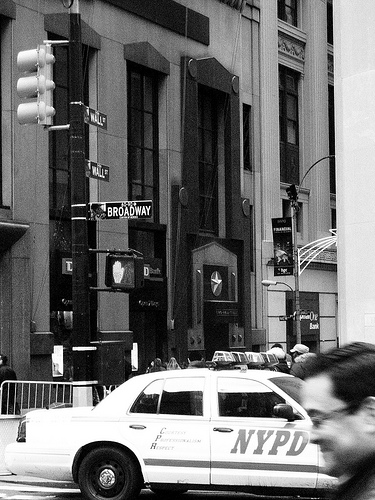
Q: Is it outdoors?
A: Yes, it is outdoors.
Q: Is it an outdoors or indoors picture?
A: It is outdoors.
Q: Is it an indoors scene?
A: No, it is outdoors.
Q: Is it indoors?
A: No, it is outdoors.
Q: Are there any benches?
A: No, there are no benches.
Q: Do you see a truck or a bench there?
A: No, there are no benches or trucks.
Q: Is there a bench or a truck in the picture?
A: No, there are no benches or trucks.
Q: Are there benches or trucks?
A: No, there are no benches or trucks.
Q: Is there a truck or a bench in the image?
A: No, there are no benches or trucks.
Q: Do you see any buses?
A: No, there are no buses.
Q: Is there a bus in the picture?
A: No, there are no buses.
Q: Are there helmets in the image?
A: No, there are no helmets.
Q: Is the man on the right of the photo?
A: Yes, the man is on the right of the image.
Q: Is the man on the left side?
A: No, the man is on the right of the image.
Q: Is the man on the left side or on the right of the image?
A: The man is on the right of the image.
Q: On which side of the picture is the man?
A: The man is on the right of the image.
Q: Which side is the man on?
A: The man is on the right of the image.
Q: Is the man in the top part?
A: No, the man is in the bottom of the image.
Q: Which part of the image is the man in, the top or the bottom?
A: The man is in the bottom of the image.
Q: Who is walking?
A: The man is walking.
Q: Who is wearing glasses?
A: The man is wearing glasses.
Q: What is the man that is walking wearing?
A: The man is wearing glasses.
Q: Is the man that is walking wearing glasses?
A: Yes, the man is wearing glasses.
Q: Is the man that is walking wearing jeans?
A: No, the man is wearing glasses.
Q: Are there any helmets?
A: No, there are no helmets.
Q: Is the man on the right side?
A: Yes, the man is on the right of the image.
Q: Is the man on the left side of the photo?
A: No, the man is on the right of the image.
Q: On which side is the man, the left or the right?
A: The man is on the right of the image.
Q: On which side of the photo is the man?
A: The man is on the right of the image.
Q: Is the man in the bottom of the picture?
A: Yes, the man is in the bottom of the image.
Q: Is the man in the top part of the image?
A: No, the man is in the bottom of the image.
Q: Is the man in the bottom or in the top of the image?
A: The man is in the bottom of the image.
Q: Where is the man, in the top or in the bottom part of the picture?
A: The man is in the bottom of the image.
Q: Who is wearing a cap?
A: The man is wearing a cap.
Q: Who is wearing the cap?
A: The man is wearing a cap.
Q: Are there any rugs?
A: No, there are no rugs.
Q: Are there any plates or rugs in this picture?
A: No, there are no rugs or plates.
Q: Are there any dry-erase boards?
A: No, there are no dry-erase boards.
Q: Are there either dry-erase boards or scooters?
A: No, there are no dry-erase boards or scooters.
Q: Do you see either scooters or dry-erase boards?
A: No, there are no dry-erase boards or scooters.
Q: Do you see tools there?
A: No, there are no tools.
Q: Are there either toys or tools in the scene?
A: No, there are no tools or toys.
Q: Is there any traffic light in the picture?
A: Yes, there is a traffic light.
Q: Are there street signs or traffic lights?
A: Yes, there is a traffic light.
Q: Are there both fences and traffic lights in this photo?
A: Yes, there are both a traffic light and a fence.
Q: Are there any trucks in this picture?
A: No, there are no trucks.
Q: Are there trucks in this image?
A: No, there are no trucks.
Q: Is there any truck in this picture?
A: No, there are no trucks.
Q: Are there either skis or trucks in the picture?
A: No, there are no trucks or skis.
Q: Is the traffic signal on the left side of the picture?
A: Yes, the traffic signal is on the left of the image.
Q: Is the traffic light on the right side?
A: No, the traffic light is on the left of the image.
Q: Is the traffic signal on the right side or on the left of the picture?
A: The traffic signal is on the left of the image.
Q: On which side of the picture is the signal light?
A: The signal light is on the left of the image.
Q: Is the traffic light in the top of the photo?
A: Yes, the traffic light is in the top of the image.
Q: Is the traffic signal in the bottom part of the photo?
A: No, the traffic signal is in the top of the image.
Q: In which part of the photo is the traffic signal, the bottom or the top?
A: The traffic signal is in the top of the image.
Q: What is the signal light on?
A: The signal light is on the pole.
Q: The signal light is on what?
A: The signal light is on the pole.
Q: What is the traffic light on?
A: The signal light is on the pole.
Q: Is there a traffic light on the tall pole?
A: Yes, there is a traffic light on the pole.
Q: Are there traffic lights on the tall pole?
A: Yes, there is a traffic light on the pole.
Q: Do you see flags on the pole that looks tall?
A: No, there is a traffic light on the pole.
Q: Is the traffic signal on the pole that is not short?
A: Yes, the traffic signal is on the pole.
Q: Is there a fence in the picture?
A: Yes, there is a fence.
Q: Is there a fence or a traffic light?
A: Yes, there is a fence.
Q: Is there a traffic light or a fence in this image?
A: Yes, there is a fence.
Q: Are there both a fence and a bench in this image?
A: No, there is a fence but no benches.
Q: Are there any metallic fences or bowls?
A: Yes, there is a metal fence.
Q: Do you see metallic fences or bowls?
A: Yes, there is a metal fence.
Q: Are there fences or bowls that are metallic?
A: Yes, the fence is metallic.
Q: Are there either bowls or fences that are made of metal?
A: Yes, the fence is made of metal.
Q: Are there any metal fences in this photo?
A: Yes, there is a metal fence.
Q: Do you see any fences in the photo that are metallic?
A: Yes, there is a fence that is metallic.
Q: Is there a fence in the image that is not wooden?
A: Yes, there is a metallic fence.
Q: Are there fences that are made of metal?
A: Yes, there is a fence that is made of metal.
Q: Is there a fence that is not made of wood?
A: Yes, there is a fence that is made of metal.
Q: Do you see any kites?
A: No, there are no kites.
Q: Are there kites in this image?
A: No, there are no kites.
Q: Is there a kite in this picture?
A: No, there are no kites.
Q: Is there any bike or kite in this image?
A: No, there are no kites or bikes.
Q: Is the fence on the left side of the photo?
A: Yes, the fence is on the left of the image.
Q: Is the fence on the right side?
A: No, the fence is on the left of the image.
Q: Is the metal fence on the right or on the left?
A: The fence is on the left of the image.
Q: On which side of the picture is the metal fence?
A: The fence is on the left of the image.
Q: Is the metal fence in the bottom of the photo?
A: Yes, the fence is in the bottom of the image.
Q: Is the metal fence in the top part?
A: No, the fence is in the bottom of the image.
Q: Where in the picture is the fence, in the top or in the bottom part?
A: The fence is in the bottom of the image.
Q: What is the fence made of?
A: The fence is made of metal.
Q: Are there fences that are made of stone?
A: No, there is a fence but it is made of metal.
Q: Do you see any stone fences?
A: No, there is a fence but it is made of metal.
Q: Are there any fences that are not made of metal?
A: No, there is a fence but it is made of metal.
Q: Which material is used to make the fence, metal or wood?
A: The fence is made of metal.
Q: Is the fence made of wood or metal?
A: The fence is made of metal.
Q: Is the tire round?
A: Yes, the tire is round.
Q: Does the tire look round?
A: Yes, the tire is round.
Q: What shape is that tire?
A: The tire is round.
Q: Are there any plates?
A: No, there are no plates.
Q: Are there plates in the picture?
A: No, there are no plates.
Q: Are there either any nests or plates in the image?
A: No, there are no plates or nests.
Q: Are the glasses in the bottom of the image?
A: Yes, the glasses are in the bottom of the image.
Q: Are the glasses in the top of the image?
A: No, the glasses are in the bottom of the image.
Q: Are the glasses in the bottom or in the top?
A: The glasses are in the bottom of the image.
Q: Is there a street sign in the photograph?
A: Yes, there is a street sign.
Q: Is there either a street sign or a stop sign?
A: Yes, there is a street sign.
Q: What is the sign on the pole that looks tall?
A: The sign is a street sign.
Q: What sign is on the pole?
A: The sign is a street sign.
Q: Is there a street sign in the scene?
A: Yes, there is a street sign.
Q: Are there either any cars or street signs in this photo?
A: Yes, there is a street sign.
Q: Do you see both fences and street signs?
A: Yes, there are both a street sign and a fence.